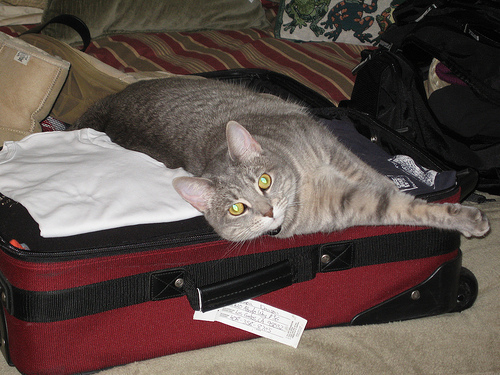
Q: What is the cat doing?
A: Laying down.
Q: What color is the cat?
A: Gray.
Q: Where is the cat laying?
A: Suitcase.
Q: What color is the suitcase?
A: Red.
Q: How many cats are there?
A: One.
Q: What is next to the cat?
A: Shirt.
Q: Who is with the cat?
A: No one.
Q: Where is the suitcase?
A: Bed.